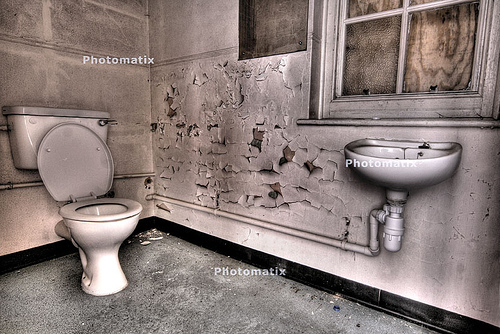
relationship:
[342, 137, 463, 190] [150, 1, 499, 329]
basin in front of wall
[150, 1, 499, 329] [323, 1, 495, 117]
wall has window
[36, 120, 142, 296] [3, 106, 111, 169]
toilet has tank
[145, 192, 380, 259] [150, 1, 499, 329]
pipe attached to wall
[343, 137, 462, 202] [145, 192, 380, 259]
sink connected to pipe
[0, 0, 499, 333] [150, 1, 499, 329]
room has wall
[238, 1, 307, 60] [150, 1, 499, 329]
mirror in front of wall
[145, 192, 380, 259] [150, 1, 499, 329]
pipe connected to wall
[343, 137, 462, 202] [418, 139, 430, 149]
sink has tap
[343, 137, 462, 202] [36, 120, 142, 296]
sink across from toilet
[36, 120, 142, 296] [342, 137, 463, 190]
toilet across from basin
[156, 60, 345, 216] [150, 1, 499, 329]
paint coming off of wall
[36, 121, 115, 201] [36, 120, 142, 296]
lid connected to toilet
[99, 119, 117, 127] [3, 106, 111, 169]
handle connected to tank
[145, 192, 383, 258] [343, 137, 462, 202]
plumbing connected to sink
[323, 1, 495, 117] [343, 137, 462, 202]
window behind sink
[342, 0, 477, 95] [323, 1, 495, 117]
plywood covering window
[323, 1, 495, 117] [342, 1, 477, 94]
window has boards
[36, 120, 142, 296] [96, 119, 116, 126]
toilet has flush control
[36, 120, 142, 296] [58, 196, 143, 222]
toilet has toilet seat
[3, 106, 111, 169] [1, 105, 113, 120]
tank has cover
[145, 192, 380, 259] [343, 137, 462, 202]
pipe going towards sink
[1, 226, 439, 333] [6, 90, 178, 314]
floor of toilet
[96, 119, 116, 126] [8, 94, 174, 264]
flush control of toilet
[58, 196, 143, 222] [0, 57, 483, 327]
toilet seat of bathroom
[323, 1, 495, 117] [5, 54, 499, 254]
window in room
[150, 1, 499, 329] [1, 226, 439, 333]
wall and floor